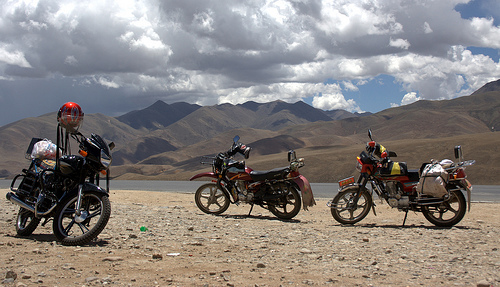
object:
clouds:
[0, 7, 367, 96]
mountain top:
[0, 79, 500, 184]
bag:
[416, 160, 449, 198]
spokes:
[201, 187, 224, 209]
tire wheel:
[194, 182, 230, 216]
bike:
[327, 127, 477, 227]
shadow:
[327, 223, 480, 231]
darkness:
[142, 106, 176, 117]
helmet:
[56, 101, 85, 128]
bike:
[4, 122, 111, 246]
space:
[364, 85, 402, 109]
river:
[0, 178, 499, 204]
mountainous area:
[0, 77, 500, 186]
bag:
[29, 138, 63, 159]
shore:
[247, 205, 254, 217]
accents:
[368, 141, 375, 148]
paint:
[390, 161, 401, 176]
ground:
[1, 180, 497, 287]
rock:
[255, 261, 265, 268]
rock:
[257, 244, 268, 249]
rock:
[300, 246, 311, 253]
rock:
[305, 251, 322, 260]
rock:
[167, 250, 179, 257]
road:
[1, 183, 500, 285]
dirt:
[0, 187, 499, 283]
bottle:
[140, 225, 148, 232]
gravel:
[0, 184, 499, 287]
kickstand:
[402, 209, 408, 226]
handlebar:
[59, 122, 85, 137]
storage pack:
[434, 158, 454, 168]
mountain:
[0, 78, 500, 185]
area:
[110, 95, 201, 131]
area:
[108, 132, 178, 167]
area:
[268, 115, 293, 128]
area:
[265, 96, 334, 123]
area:
[236, 98, 262, 113]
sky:
[0, 0, 500, 126]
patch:
[325, 73, 412, 110]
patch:
[299, 91, 321, 104]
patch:
[463, 43, 484, 61]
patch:
[451, 1, 483, 20]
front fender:
[189, 172, 239, 206]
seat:
[250, 166, 290, 180]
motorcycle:
[189, 135, 319, 219]